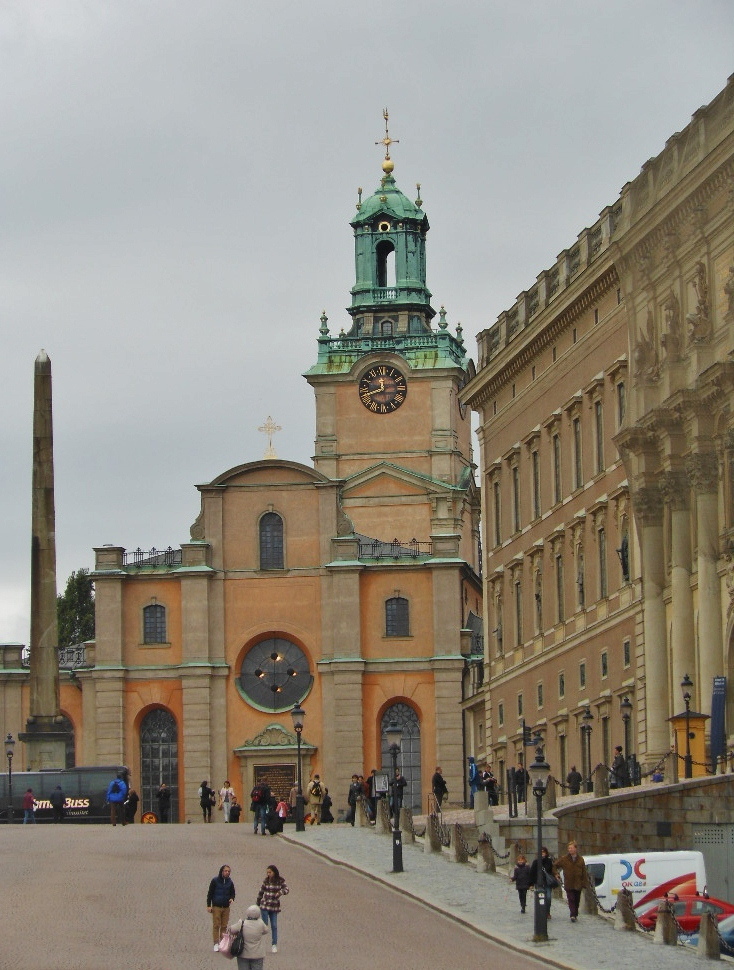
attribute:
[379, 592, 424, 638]
window — on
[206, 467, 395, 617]
wall — side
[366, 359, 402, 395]
hands — yellow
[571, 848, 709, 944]
van — white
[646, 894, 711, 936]
car — red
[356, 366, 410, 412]
face — black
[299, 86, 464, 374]
top — green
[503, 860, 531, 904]
person — walking